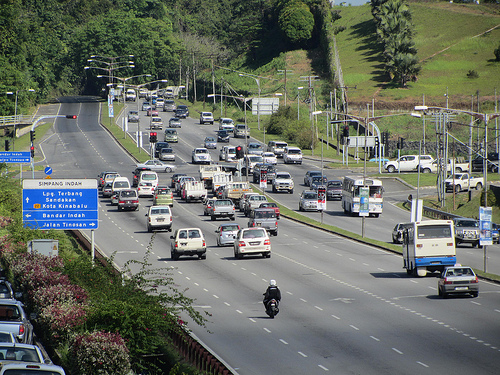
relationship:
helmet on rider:
[263, 275, 281, 285] [261, 271, 282, 317]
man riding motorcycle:
[263, 279, 281, 310] [260, 295, 286, 317]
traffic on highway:
[99, 88, 481, 328] [39, 97, 498, 372]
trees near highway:
[0, 2, 321, 108] [39, 97, 498, 372]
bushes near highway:
[45, 223, 215, 371] [39, 97, 498, 372]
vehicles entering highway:
[402, 218, 464, 281] [39, 97, 498, 372]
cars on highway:
[435, 264, 481, 298] [13, 95, 500, 375]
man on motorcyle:
[263, 279, 281, 310] [265, 286, 280, 320]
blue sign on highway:
[19, 176, 99, 232] [39, 97, 498, 372]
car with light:
[113, 187, 138, 212] [130, 197, 140, 202]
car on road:
[145, 205, 173, 233] [332, 294, 356, 339]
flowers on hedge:
[34, 275, 87, 310] [21, 276, 91, 333]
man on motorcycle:
[264, 272, 283, 299] [257, 286, 281, 318]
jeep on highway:
[231, 216, 275, 256] [57, 67, 464, 374]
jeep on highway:
[148, 187, 176, 209] [68, 115, 118, 167]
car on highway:
[233, 227, 272, 260] [13, 95, 500, 375]